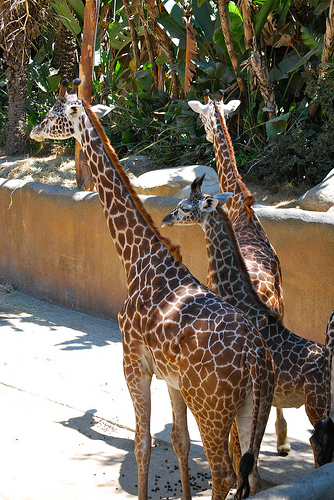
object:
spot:
[231, 385, 241, 405]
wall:
[179, 233, 202, 241]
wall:
[92, 289, 102, 304]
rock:
[130, 165, 220, 199]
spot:
[192, 394, 203, 406]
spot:
[316, 395, 324, 409]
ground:
[100, 479, 116, 500]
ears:
[201, 197, 219, 212]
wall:
[293, 227, 332, 273]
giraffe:
[29, 77, 276, 500]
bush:
[245, 128, 334, 184]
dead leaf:
[182, 16, 199, 96]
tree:
[0, 0, 60, 157]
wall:
[0, 210, 53, 264]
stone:
[155, 479, 158, 482]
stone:
[202, 488, 207, 491]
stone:
[165, 460, 167, 463]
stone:
[116, 488, 118, 490]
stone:
[197, 473, 200, 475]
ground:
[2, 480, 67, 497]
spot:
[215, 230, 226, 243]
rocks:
[154, 459, 173, 492]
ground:
[76, 324, 95, 349]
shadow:
[55, 334, 112, 352]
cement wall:
[0, 178, 334, 345]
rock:
[296, 168, 334, 212]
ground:
[0, 361, 15, 395]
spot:
[170, 338, 181, 355]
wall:
[39, 279, 56, 297]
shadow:
[53, 408, 212, 499]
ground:
[1, 475, 38, 494]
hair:
[309, 417, 333, 468]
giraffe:
[187, 88, 291, 456]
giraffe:
[160, 172, 334, 468]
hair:
[233, 452, 254, 499]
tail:
[238, 359, 260, 487]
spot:
[201, 348, 213, 366]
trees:
[120, 0, 179, 101]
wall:
[103, 298, 116, 316]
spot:
[224, 395, 232, 410]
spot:
[112, 184, 126, 204]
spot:
[218, 264, 230, 284]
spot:
[89, 142, 100, 154]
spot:
[123, 317, 131, 346]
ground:
[98, 363, 117, 411]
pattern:
[192, 361, 226, 419]